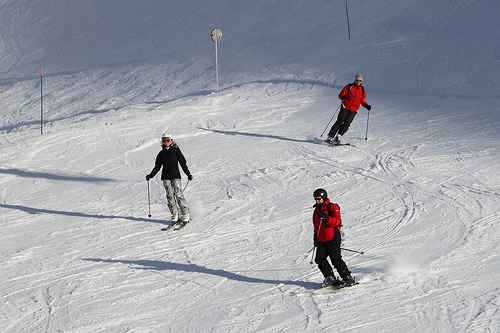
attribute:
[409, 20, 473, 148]
snow — white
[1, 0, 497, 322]
snow — white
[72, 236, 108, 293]
snow — white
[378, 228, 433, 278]
snow — white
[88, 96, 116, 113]
snow — white 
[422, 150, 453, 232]
snow — white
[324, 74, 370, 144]
man — in red, in black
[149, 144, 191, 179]
coat — black 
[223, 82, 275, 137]
snow — white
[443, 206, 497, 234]
snow — white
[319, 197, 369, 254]
jacket — red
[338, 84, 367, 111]
jacket — red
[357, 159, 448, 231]
snow — white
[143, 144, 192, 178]
jacket — black